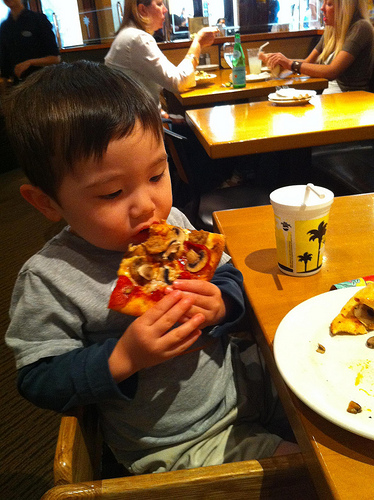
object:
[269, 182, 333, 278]
cup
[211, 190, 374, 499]
table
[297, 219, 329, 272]
palm tree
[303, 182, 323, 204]
straw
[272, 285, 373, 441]
plate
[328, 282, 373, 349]
food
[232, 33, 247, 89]
bottle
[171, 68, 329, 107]
table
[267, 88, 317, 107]
plates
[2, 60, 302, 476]
boy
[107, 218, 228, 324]
pizza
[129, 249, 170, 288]
mushrooms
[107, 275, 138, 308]
pepperoni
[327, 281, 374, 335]
pizza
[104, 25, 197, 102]
shirt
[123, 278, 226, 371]
hands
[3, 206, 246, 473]
shirt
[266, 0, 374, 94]
woman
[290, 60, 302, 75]
bracelets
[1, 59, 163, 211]
hair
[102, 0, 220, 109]
women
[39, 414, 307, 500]
high chair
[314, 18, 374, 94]
shirt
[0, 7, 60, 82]
shirt